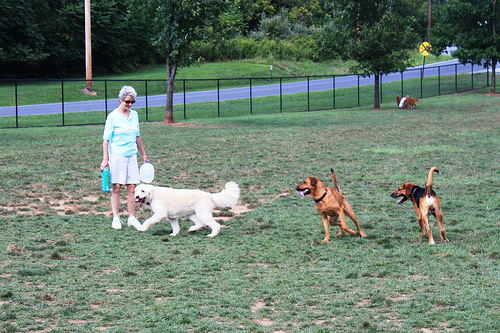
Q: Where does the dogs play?
A: In field.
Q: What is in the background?
A: Trees.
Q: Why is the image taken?
A: Remembrance.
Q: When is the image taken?
A: Dogs are running.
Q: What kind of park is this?
A: Dog park.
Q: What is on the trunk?
A: Mud.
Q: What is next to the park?
A: Street.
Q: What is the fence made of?
A: Chain link.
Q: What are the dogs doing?
A: Running.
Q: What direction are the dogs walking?
A: Left.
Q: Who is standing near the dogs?
A: An adult woman.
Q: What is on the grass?
A: Leaves.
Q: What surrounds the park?
A: Fence.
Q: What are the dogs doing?
A: Playing together.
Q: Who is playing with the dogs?
A: Older woman.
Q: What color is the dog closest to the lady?
A: White.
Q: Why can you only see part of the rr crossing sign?
A: Trees.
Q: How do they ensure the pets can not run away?
A: Fence.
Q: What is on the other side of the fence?
A: Road.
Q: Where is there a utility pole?
A: Other side road.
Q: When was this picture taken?
A: Daytime.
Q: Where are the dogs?
A: Dog park.